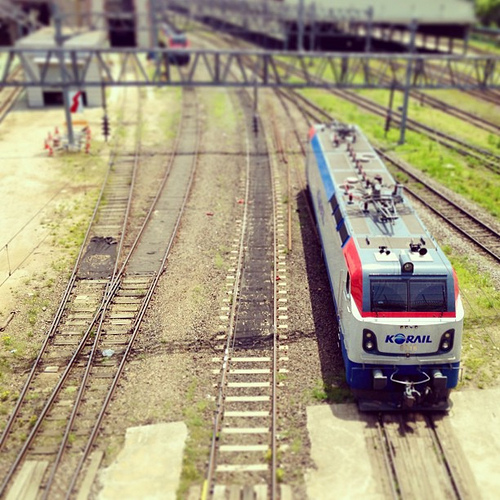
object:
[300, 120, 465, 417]
train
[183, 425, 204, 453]
grass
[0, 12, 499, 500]
ground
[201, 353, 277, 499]
railroad tracks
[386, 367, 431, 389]
bumper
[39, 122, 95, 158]
cones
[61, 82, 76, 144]
pole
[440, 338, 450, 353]
headlight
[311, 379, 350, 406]
grass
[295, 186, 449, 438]
shadow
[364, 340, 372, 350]
lights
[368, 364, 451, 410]
link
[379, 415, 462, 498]
rail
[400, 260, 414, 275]
light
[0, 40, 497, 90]
rail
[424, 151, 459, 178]
weeds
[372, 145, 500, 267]
tracks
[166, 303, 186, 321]
gravel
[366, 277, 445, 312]
winshield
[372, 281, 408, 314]
reflection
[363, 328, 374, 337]
headlight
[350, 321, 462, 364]
front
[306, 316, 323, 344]
gravel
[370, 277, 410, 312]
window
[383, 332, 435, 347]
brand name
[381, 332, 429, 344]
train company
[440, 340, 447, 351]
headlights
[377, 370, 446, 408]
hook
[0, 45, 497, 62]
railing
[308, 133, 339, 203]
stripe